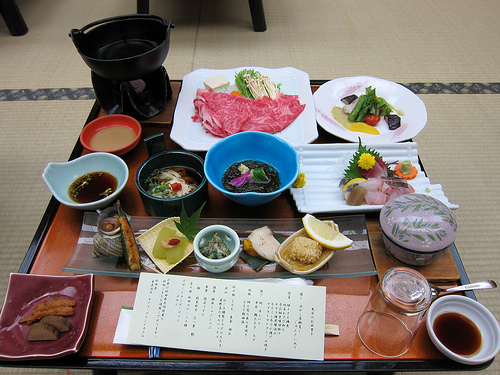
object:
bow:
[40, 150, 132, 215]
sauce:
[40, 163, 133, 208]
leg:
[1, 0, 29, 38]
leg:
[246, 0, 268, 32]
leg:
[136, 0, 151, 17]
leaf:
[173, 196, 201, 239]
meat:
[190, 81, 308, 136]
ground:
[308, 172, 339, 210]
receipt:
[126, 270, 326, 363]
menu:
[124, 267, 330, 364]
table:
[4, 72, 492, 373]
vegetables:
[330, 85, 407, 136]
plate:
[311, 76, 429, 146]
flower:
[353, 152, 378, 172]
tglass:
[356, 266, 431, 358]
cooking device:
[65, 2, 206, 123]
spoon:
[407, 278, 494, 298]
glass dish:
[336, 249, 376, 274]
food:
[241, 224, 284, 263]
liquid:
[433, 312, 481, 358]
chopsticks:
[323, 322, 340, 335]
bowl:
[75, 113, 144, 158]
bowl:
[134, 150, 212, 215]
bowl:
[193, 222, 245, 275]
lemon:
[301, 212, 354, 250]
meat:
[23, 297, 76, 344]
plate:
[289, 140, 460, 215]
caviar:
[221, 159, 282, 194]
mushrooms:
[242, 72, 282, 97]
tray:
[7, 78, 487, 372]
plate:
[171, 65, 319, 151]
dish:
[381, 191, 455, 264]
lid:
[379, 190, 456, 250]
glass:
[357, 260, 428, 362]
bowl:
[202, 130, 302, 203]